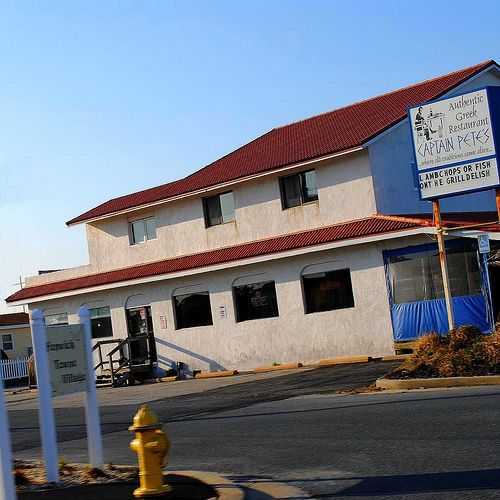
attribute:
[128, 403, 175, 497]
fire hydrant — yellow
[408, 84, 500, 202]
sign — white, here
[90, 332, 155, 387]
staircase — wooden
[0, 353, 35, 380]
fence — white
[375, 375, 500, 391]
curb — yellow, concrete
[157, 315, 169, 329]
handicapped sign — here, blue, white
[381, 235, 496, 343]
tarp — blue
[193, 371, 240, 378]
marker — yellow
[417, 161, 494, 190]
letters — black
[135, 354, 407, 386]
blocks — yellow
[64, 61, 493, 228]
roof — red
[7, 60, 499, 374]
restaurant — greek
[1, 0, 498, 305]
sky — blue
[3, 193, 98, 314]
clouds — white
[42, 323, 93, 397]
sign — white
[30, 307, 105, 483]
posts — white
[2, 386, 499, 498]
road — black